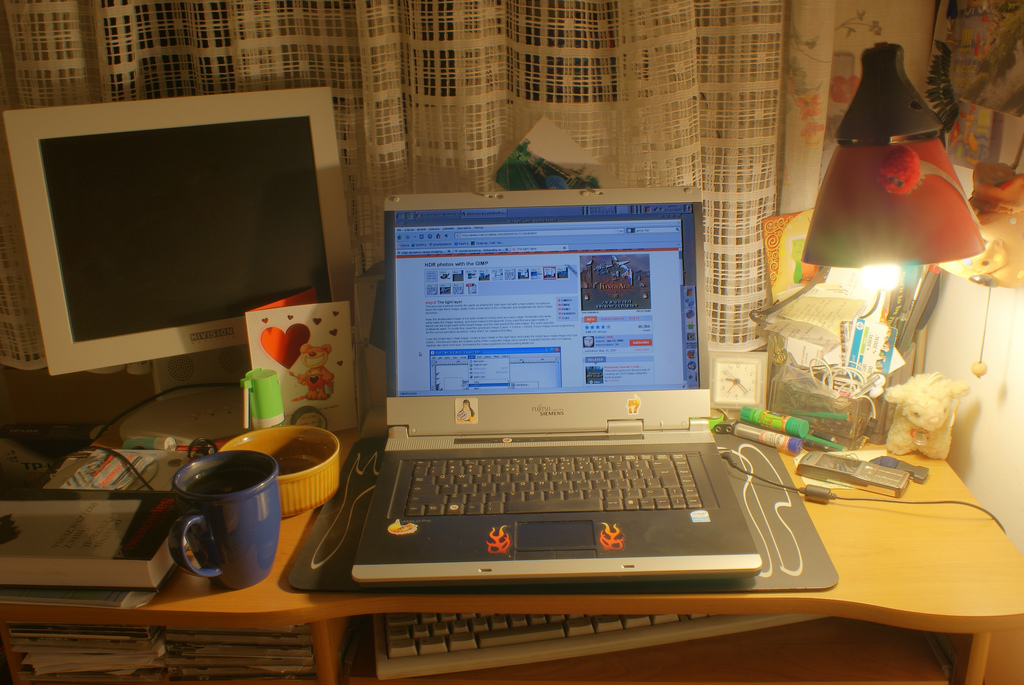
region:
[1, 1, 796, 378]
Curtains that look like lace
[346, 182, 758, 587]
Laptop with flame stickers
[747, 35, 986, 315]
Desk lamp with puffy sticker on it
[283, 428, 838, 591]
Black pad with cutlery markings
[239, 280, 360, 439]
Valentine's Day greeting card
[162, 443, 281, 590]
Blue ceramic mug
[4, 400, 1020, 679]
Small wooden computer desk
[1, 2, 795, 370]
Closed window showing nighttime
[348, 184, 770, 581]
Laptop viewing a website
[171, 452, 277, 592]
a dark blue coffee mug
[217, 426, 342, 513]
a yellow ceramic bowl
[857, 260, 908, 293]
a light bulb under the lampshade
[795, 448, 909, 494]
a wireless phone on the table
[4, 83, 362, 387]
an old CRT on the table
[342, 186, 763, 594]
a small laptop on the table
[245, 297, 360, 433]
a card sitting by the laptop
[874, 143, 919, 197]
a fluffy red ball on the lampshade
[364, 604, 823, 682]
a keyboard on a lower shelf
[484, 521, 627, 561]
a couple of stickers on the laptop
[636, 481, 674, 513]
key on the keyboard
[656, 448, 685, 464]
key on the keyboard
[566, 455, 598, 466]
key on the keyboard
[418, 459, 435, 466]
key on the keyboard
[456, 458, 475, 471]
key on the keyboard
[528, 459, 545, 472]
key on the keyboard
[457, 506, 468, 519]
key on the keyboard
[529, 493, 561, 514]
key on the keyboard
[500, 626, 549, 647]
key on the keyboard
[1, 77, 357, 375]
The white computer monitor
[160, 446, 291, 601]
The blue mug sitting on the desk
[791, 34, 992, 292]
The lamp illuminating the desk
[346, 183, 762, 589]
The laptop sitting on the desk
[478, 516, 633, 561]
The flame stickers on the laptop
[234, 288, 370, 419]
The red and white card next to the laptop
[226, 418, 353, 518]
The yellow bowl behing the blue mug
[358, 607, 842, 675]
The white keyboard under the laptop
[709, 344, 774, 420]
The clock to the right of the laptop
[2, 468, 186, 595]
The book next to the blue mug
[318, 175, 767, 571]
open silver laptop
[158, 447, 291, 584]
blue mug on the desk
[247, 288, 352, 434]
white and red greeting card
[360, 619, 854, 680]
white keyboard below the laptop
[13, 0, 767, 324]
white curtain behind the laptop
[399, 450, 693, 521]
keyboard on the laptop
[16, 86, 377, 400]
computer monitor with white frame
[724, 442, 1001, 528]
black cord attached to the laptop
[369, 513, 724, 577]
stickers on the silver laptop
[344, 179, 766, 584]
laptop computer on desk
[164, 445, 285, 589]
blue coffee mug next to laptop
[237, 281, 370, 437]
card with a bear and a heart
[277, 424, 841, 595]
play mat with pictures of cutlery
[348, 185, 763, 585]
The laptop is opened.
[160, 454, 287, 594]
The cup is blue in color.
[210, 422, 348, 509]
The bowl is yellow in color.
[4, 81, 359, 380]
The computer frame is white in color.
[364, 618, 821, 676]
The computer keyboard is white in color.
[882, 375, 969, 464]
The teddy bear is white in color.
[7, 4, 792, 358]
The blinds are white in color.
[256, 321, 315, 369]
The heart is red in color.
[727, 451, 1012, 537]
The laptop wire is black in color.